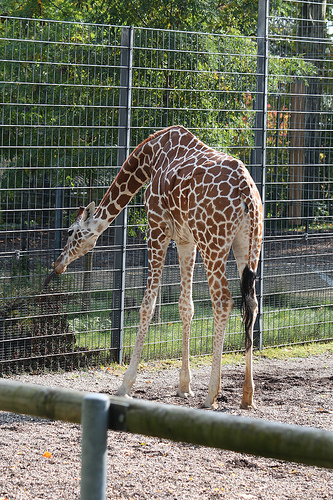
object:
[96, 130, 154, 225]
neck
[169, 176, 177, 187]
spot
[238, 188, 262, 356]
tail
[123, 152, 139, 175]
spot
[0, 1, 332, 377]
pen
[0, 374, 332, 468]
pole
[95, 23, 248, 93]
fence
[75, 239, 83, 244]
spot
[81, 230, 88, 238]
spot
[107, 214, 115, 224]
spot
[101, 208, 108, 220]
spot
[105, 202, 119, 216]
spot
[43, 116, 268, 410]
giraffe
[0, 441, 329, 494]
ground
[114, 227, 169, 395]
legs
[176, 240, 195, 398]
legs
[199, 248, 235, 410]
legs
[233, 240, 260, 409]
legs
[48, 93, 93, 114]
leaves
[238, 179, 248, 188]
spot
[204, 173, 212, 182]
spot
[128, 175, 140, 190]
spot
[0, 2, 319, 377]
fence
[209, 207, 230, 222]
spot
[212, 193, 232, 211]
spot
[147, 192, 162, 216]
spot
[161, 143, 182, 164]
spot